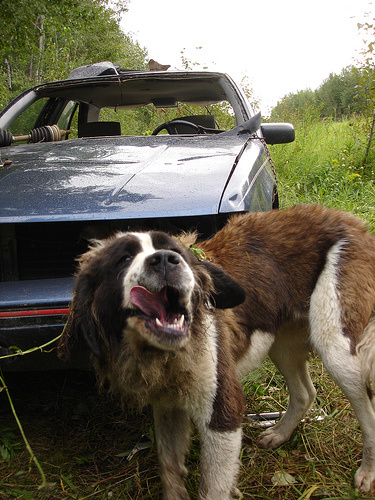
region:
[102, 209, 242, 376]
the head of a dog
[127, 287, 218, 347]
the teeth of a dog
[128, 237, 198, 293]
the nose of a dog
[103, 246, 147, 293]
the eye of a dog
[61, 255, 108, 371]
the ear of a dog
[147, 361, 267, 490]
the legs of a dog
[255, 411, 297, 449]
the paw of a dog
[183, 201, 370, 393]
the body of a dog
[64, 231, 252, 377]
the mouth of a dog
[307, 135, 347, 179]
patch of green grass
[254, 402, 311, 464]
leg of the dog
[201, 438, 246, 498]
leg of the dog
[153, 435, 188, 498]
leg of the dog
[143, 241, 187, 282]
nose of the dog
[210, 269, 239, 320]
ear of the dog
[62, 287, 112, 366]
ear of the dog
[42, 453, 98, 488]
patch of green grass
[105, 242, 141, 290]
the eye of a dog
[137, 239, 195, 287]
the nose of a dog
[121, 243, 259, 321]
the mouth of a dog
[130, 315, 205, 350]
the teeth of a dog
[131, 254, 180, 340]
the tongue of a dog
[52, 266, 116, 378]
the ear of a dog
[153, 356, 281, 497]
the legs of a dog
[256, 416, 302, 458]
the paw of a dog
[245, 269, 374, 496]
the back legs of a dog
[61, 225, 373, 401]
dog next to car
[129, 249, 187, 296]
dog has black nose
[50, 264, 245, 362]
dog has brown ears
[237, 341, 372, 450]
dog has white paws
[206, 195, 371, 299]
dog has brown back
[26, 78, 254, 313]
blue car behind dog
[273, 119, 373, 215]
green and tall grass behind car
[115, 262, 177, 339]
dog has pink tongue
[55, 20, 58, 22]
A green leaf on a plant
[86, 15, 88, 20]
A green leaf on a plant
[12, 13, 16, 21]
A green leaf on a plant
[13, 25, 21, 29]
A green leaf on a plant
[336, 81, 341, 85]
A green leaf on a plant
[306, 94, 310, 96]
A green leaf on a plant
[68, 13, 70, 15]
A green leaf on a plant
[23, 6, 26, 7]
A green leaf on a plant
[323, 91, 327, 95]
A green leaf on a plant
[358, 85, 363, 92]
A green leaf on a plant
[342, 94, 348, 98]
A green leaf on a plant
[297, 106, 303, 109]
A green leaf on a plant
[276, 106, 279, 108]
A green leaf on a plant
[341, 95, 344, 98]
A green leaf on a plant